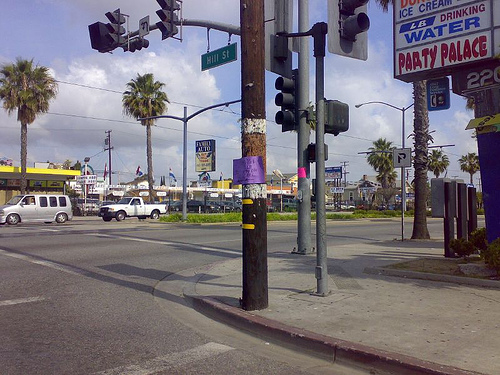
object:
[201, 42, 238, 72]
sign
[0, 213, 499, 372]
street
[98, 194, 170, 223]
truck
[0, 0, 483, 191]
sky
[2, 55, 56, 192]
tree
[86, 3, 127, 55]
traffic signals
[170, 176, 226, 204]
property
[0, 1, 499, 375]
background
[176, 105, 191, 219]
pole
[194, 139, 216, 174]
sign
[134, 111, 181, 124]
lamp post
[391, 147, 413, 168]
sign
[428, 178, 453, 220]
telephone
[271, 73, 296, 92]
light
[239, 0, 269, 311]
pole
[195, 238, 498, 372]
sidewalk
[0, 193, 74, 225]
van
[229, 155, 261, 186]
flyer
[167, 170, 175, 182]
flag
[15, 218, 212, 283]
crosswalk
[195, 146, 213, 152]
auto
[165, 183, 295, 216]
auto dealer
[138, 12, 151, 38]
directional sign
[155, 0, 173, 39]
traffic light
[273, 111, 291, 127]
light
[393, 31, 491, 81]
logo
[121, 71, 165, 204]
tree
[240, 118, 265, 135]
paint